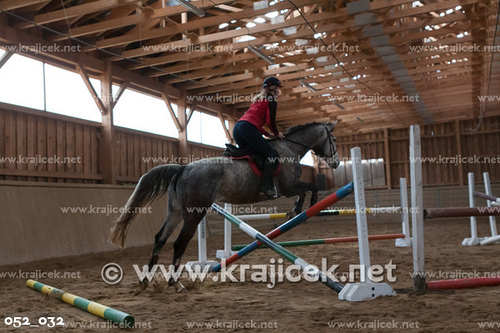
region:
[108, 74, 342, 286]
A female on a horse.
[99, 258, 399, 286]
A white copy right mark.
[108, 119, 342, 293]
A dark horse jumping.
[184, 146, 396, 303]
A multicolored horse hurdle.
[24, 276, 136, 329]
Green and yellow pipe.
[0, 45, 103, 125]
A large bright window.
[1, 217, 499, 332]
Area of brown dirt.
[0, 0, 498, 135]
Ceiling brown wood beams.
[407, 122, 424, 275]
A white hurdle pole.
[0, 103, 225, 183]
A brown wood wall.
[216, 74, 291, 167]
this is a woman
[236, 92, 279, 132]
woman wearing red shirt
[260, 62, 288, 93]
woman wearing black hat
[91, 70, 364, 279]
woman riding a horse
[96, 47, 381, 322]
horse making a jump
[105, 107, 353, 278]
horse is grey and black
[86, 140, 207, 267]
horse tail is grey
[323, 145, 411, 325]
white post of hurdle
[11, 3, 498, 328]
an indoor horse arena has wood beams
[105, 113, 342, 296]
the horse is jumping over a cross jump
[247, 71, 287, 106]
the rider has a helmet on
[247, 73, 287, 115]
the rider has long hair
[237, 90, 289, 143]
a red shirt is on the rider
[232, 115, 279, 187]
black riding pants are on the girl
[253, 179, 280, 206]
the lady's foot is in the stirrup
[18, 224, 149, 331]
a pole has been knocked on the ground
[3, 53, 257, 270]
the arena has an open upper wall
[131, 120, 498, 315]
several jumps are in the arena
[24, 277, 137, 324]
A green and yellow jump pole used for horse training.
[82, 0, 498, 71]
An opened roof barn.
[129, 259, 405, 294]
An advertisement for a website.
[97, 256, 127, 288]
The copyright symbol.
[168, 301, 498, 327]
Mud on the floor of a barn.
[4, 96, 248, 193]
A wooden protection fence for stables.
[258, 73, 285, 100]
A lady with a black jockey hat on.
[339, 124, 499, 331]
Training poles used for training horses.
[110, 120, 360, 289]
A gray horse prancing in the air.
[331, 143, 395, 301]
a white pole with a base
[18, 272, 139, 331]
a green and yellow pole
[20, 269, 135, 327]
a pole on the ground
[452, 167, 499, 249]
two poles with a base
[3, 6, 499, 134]
the roof is made of wood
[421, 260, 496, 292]
a red pole on the ground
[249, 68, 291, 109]
woman holds a black helmet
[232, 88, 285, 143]
a red and black jacket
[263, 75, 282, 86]
the helmet is black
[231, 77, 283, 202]
the person wearing the helmet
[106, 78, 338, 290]
the person on the horse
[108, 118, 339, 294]
he horse getting ready to jump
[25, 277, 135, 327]
the pole is yellow and green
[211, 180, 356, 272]
the pole is red and blue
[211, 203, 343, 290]
the pole is green and white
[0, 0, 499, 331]
the horse in the structure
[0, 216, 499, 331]
the dirt is brown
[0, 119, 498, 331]
the horse on the dirt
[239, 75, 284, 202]
the girl is on the horse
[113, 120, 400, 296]
the horse is going over a jump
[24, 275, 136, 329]
a green and yellow pole on the ground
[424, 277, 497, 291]
a red pole is on the ground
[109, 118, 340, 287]
the horse is dappled grey